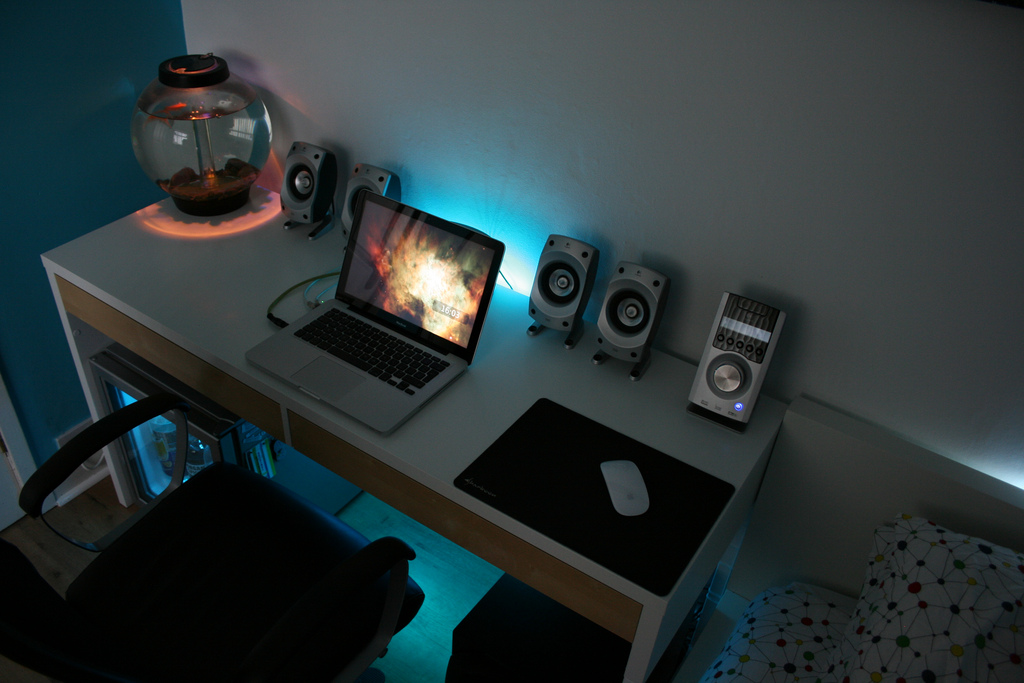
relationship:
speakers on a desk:
[510, 225, 671, 379] [166, 223, 854, 664]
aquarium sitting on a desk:
[104, 35, 275, 262] [71, 190, 784, 638]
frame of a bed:
[739, 402, 1005, 604] [745, 409, 1016, 677]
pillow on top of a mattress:
[840, 504, 994, 664] [743, 571, 862, 677]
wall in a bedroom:
[8, 18, 220, 408] [30, 7, 973, 666]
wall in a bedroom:
[166, 22, 1018, 431] [21, 24, 1017, 627]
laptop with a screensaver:
[244, 191, 504, 439] [345, 212, 525, 396]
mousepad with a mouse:
[460, 381, 744, 604] [587, 432, 667, 543]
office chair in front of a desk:
[2, 404, 441, 677] [38, 138, 786, 679]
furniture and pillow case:
[855, 532, 1002, 677] [827, 521, 966, 669]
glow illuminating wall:
[432, 197, 558, 314] [326, 13, 798, 485]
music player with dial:
[665, 275, 778, 463] [704, 342, 761, 418]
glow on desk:
[132, 203, 327, 247] [38, 138, 786, 679]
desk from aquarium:
[38, 138, 786, 679] [126, 49, 276, 219]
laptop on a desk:
[244, 201, 487, 482] [38, 138, 786, 679]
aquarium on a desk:
[126, 49, 276, 219] [69, 195, 867, 636]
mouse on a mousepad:
[587, 432, 667, 543] [443, 376, 755, 631]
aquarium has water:
[126, 49, 276, 219] [128, 90, 288, 227]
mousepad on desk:
[447, 398, 738, 596] [38, 138, 786, 679]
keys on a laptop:
[294, 307, 435, 387] [244, 191, 504, 439]